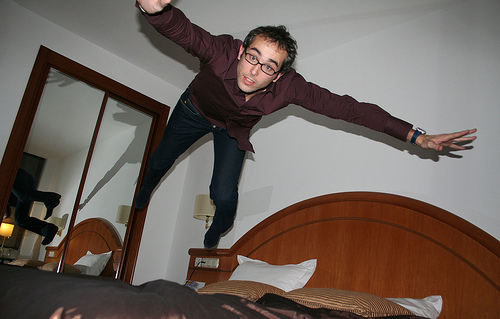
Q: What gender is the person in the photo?
A: Male.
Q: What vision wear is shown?
A: Glasses.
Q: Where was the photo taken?
A: Bedroom.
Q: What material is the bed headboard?
A: Wood.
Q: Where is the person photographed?
A: In the air.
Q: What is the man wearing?
A: Long sleeve shirt.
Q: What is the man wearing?
A: A dress shirt.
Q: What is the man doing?
A: Jumping on bed.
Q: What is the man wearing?
A: Maroon shirt.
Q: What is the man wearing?
A: Dark blue jeans.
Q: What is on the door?
A: A mirror.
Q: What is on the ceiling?
A: Man's shadow.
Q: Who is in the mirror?
A: A man.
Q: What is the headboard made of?
A: Wood.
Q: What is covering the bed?
A: A brown comforter.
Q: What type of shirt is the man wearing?
A: Red button-up.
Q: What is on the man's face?
A: Glasses.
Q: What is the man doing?
A: Leaping into the bed.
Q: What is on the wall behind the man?
A: A large mirror.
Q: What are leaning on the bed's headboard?
A: Pillows.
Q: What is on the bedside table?
A: A lamp.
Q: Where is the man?
A: In the air.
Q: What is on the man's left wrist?
A: Watch.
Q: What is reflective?
A: The mirror.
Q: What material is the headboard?
A: Wooden.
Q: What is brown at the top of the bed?
A: The headboard.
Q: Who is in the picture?
A: A man.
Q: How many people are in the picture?
A: One.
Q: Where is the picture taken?
A: A bedroom.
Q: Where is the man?
A: The air.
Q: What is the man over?
A: A bed.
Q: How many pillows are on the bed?
A: 4.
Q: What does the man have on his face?
A: Glasses.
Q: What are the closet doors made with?
A: Mirrors.